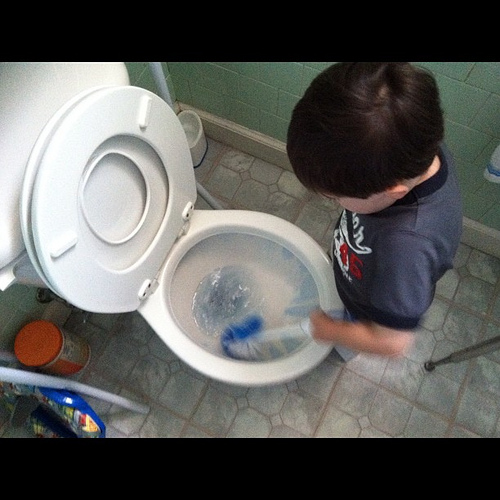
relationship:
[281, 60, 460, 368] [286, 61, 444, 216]
person has a head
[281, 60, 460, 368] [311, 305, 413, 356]
person has an arm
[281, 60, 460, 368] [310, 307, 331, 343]
person has a hand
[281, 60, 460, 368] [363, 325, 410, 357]
person has an elbow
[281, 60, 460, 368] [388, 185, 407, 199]
person has an ear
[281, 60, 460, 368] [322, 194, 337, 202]
person has an eyebrow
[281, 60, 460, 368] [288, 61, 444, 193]
person has hair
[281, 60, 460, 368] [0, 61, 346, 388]
person scrubbing toilet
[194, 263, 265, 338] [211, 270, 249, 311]
water has soap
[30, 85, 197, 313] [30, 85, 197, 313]
toilet seat on toilet seat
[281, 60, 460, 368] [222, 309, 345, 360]
person holding toilet brush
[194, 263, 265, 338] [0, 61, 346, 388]
water in toilet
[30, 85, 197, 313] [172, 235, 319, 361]
toilet seat has a toilet bowl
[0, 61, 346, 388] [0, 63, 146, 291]
toilet has a tank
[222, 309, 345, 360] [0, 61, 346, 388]
toilet brush in toilet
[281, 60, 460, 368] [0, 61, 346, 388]
person cleaning toilet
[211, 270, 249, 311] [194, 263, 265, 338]
soap in water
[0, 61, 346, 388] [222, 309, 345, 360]
toilet being cleaned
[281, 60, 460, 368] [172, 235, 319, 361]
person cleaning toilet bowl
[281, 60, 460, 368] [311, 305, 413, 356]
person has arm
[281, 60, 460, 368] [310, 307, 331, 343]
person has hand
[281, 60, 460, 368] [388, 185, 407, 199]
person has ear